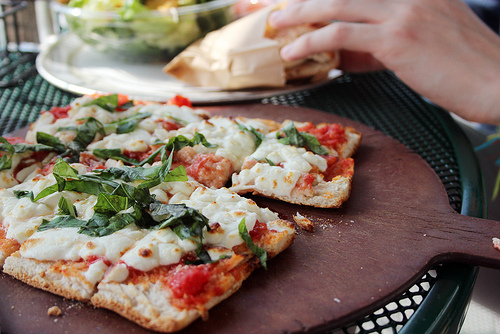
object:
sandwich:
[267, 7, 342, 81]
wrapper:
[156, 8, 295, 88]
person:
[263, 1, 499, 122]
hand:
[264, 0, 499, 124]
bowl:
[47, 0, 242, 70]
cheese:
[61, 223, 151, 273]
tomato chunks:
[163, 250, 238, 322]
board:
[0, 89, 476, 328]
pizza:
[3, 93, 498, 333]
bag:
[165, 6, 333, 85]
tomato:
[160, 260, 212, 310]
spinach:
[45, 160, 199, 230]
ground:
[330, 74, 352, 110]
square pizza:
[57, 80, 350, 249]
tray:
[1, 97, 496, 332]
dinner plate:
[28, 35, 361, 107]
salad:
[55, 1, 210, 51]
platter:
[307, 204, 447, 296]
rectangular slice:
[234, 133, 360, 214]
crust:
[2, 252, 248, 331]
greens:
[95, 8, 217, 50]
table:
[5, 28, 468, 328]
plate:
[27, 27, 356, 116]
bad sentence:
[222, 123, 396, 211]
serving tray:
[8, 87, 482, 317]